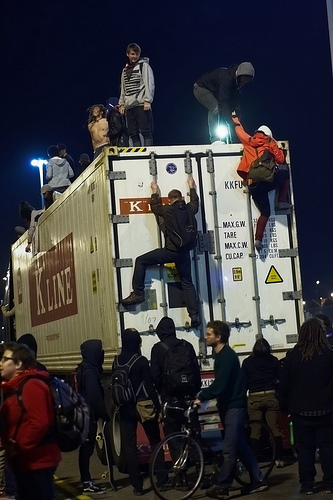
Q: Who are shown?
A: A group of men and women.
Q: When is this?
A: At night.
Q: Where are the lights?
A: Behind the truck.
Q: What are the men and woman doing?
A: Climbing the truck.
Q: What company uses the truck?
A: Kline.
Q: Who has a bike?
A: The man in the green shirt.